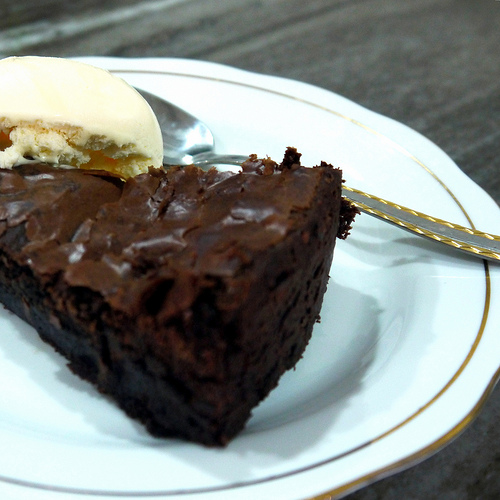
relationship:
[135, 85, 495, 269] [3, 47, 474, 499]
spoon on plate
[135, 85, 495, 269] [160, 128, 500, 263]
spoon has handle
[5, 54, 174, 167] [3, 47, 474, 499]
ice cream on plate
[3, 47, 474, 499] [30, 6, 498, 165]
plate on table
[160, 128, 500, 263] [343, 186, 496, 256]
handle has gold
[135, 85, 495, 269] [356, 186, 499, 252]
spoon has detail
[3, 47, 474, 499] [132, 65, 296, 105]
plate has detail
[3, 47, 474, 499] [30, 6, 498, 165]
plate sitting on table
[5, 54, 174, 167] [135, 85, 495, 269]
ice cream on spoon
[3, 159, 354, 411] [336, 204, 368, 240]
cake has crumb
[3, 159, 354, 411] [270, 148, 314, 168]
cake has crumb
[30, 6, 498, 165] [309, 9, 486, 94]
table has part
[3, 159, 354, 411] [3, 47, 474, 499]
cake on top of plate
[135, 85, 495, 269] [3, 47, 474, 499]
spoon on top of plate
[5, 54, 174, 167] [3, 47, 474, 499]
ice cream on top of plate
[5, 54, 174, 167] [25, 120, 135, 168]
ice cream has sauce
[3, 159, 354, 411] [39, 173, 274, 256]
cake has crust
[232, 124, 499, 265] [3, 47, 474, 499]
handle resting on plate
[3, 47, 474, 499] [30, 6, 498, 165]
plate resting on table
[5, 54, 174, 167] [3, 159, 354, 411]
ice cream next to cake